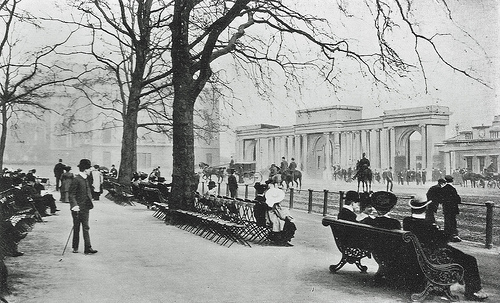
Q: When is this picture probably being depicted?
A: Daytime.